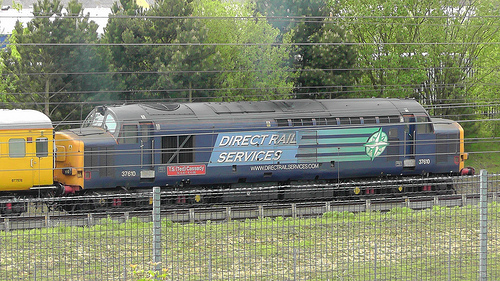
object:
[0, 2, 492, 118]
forest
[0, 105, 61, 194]
car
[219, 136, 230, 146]
letter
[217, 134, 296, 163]
compay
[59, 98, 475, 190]
engine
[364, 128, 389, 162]
logo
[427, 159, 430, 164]
numbers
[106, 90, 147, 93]
lines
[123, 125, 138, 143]
window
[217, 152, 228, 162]
letter s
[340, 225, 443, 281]
mesh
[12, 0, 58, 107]
trees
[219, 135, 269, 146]
word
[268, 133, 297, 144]
word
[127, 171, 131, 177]
numbers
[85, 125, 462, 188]
side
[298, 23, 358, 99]
tree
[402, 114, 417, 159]
door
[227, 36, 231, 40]
leaves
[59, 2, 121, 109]
trees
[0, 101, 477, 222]
train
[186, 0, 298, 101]
trees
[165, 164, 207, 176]
red sign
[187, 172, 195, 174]
white writing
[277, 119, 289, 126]
vents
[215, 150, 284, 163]
word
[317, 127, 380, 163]
painting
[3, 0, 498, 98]
background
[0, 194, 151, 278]
fence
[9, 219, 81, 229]
track